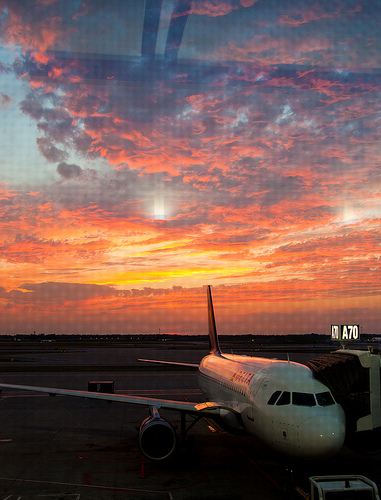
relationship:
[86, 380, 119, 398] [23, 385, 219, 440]
cart near wing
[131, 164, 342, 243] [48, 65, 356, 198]
sunlight through clouds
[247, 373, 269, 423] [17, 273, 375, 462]
door on side of plane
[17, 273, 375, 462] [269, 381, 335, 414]
plane has windows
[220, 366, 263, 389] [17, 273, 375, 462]
logo on plane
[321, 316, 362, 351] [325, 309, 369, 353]
number on sign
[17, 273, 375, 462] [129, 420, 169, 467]
plane has engine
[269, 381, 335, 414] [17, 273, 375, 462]
windows on plane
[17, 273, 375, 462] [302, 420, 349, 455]
plane has nose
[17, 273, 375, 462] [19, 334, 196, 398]
plane sits on runway